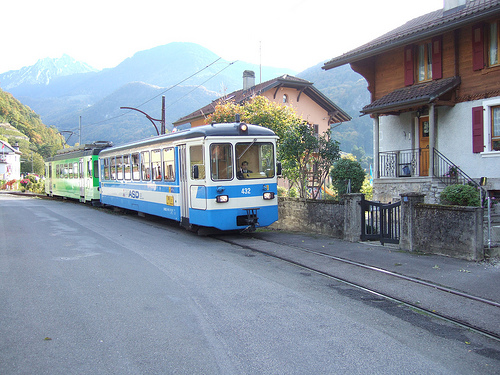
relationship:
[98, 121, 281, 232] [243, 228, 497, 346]
train on a track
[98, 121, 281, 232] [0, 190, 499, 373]
train on a street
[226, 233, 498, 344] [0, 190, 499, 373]
tracks on street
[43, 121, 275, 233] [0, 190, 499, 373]
train on a street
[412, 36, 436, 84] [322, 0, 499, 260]
window on building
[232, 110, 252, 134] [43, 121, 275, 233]
light on train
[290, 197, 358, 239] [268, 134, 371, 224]
wall around yard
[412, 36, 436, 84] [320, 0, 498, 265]
window on two story building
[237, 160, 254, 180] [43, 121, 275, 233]
conductor on a train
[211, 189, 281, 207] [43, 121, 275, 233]
lights on a train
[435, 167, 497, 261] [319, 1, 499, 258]
steps leading to a house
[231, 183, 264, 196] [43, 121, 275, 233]
numbers on a train